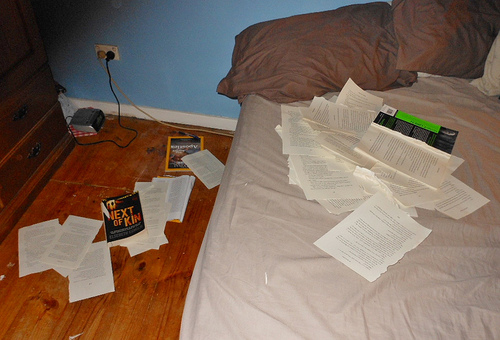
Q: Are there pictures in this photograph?
A: No, there are no pictures.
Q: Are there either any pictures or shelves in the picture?
A: No, there are no pictures or shelves.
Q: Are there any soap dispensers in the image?
A: No, there are no soap dispensers.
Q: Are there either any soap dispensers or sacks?
A: No, there are no soap dispensers or sacks.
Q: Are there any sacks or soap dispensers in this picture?
A: No, there are no soap dispensers or sacks.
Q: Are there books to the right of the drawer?
A: Yes, there is a book to the right of the drawer.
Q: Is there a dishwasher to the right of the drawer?
A: No, there is a book to the right of the drawer.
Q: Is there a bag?
A: No, there are no bags.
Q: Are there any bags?
A: No, there are no bags.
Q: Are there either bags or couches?
A: No, there are no bags or couches.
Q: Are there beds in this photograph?
A: Yes, there is a bed.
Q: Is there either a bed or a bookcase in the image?
A: Yes, there is a bed.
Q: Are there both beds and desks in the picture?
A: No, there is a bed but no desks.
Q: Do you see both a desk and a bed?
A: No, there is a bed but no desks.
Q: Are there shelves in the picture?
A: No, there are no shelves.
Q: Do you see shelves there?
A: No, there are no shelves.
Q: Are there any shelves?
A: No, there are no shelves.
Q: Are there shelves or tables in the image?
A: No, there are no shelves or tables.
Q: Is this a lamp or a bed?
A: This is a bed.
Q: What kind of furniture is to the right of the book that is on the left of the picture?
A: The piece of furniture is a bed.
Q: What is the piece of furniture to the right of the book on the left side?
A: The piece of furniture is a bed.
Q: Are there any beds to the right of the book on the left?
A: Yes, there is a bed to the right of the book.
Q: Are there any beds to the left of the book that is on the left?
A: No, the bed is to the right of the book.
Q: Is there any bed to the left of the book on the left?
A: No, the bed is to the right of the book.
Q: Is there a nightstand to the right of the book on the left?
A: No, there is a bed to the right of the book.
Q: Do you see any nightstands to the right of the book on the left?
A: No, there is a bed to the right of the book.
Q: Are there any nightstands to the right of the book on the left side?
A: No, there is a bed to the right of the book.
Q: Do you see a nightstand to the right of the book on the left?
A: No, there is a bed to the right of the book.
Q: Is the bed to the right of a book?
A: Yes, the bed is to the right of a book.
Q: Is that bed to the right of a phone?
A: No, the bed is to the right of a book.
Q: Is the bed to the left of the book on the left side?
A: No, the bed is to the right of the book.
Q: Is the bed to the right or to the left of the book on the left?
A: The bed is to the right of the book.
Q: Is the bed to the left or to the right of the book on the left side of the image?
A: The bed is to the right of the book.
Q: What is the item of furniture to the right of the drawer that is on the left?
A: The piece of furniture is a bed.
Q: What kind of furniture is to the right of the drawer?
A: The piece of furniture is a bed.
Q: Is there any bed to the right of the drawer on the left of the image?
A: Yes, there is a bed to the right of the drawer.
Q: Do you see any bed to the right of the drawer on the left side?
A: Yes, there is a bed to the right of the drawer.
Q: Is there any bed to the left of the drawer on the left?
A: No, the bed is to the right of the drawer.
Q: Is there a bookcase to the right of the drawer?
A: No, there is a bed to the right of the drawer.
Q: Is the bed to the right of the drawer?
A: Yes, the bed is to the right of the drawer.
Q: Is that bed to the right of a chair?
A: No, the bed is to the right of the drawer.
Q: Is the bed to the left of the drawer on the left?
A: No, the bed is to the right of the drawer.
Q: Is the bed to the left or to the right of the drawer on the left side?
A: The bed is to the right of the drawer.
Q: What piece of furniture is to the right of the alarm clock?
A: The piece of furniture is a bed.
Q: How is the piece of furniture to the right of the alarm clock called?
A: The piece of furniture is a bed.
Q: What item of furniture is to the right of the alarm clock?
A: The piece of furniture is a bed.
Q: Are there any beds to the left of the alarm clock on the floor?
A: No, the bed is to the right of the alarm clock.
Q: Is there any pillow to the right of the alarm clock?
A: No, there is a bed to the right of the alarm clock.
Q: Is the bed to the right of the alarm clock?
A: Yes, the bed is to the right of the alarm clock.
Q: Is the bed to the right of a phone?
A: No, the bed is to the right of the alarm clock.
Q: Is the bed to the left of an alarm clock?
A: No, the bed is to the right of an alarm clock.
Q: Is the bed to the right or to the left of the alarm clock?
A: The bed is to the right of the alarm clock.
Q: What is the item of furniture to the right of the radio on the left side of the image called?
A: The piece of furniture is a bed.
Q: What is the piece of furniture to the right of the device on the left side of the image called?
A: The piece of furniture is a bed.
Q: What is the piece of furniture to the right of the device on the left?
A: The piece of furniture is a bed.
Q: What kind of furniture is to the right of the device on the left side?
A: The piece of furniture is a bed.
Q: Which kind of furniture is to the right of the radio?
A: The piece of furniture is a bed.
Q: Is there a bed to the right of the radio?
A: Yes, there is a bed to the right of the radio.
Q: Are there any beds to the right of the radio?
A: Yes, there is a bed to the right of the radio.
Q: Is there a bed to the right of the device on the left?
A: Yes, there is a bed to the right of the radio.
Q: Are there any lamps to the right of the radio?
A: No, there is a bed to the right of the radio.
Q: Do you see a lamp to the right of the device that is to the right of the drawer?
A: No, there is a bed to the right of the radio.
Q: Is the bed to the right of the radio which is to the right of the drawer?
A: Yes, the bed is to the right of the radio.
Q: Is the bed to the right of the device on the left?
A: Yes, the bed is to the right of the radio.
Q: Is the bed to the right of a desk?
A: No, the bed is to the right of the radio.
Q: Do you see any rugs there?
A: No, there are no rugs.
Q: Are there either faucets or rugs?
A: No, there are no rugs or faucets.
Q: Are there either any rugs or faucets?
A: No, there are no rugs or faucets.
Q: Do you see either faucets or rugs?
A: No, there are no rugs or faucets.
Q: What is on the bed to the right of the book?
A: The paper is on the bed.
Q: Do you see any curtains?
A: No, there are no curtains.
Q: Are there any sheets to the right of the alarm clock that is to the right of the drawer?
A: Yes, there is a sheet to the right of the alarm clock.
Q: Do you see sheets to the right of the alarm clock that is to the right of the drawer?
A: Yes, there is a sheet to the right of the alarm clock.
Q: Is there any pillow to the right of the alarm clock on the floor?
A: No, there is a sheet to the right of the alarm clock.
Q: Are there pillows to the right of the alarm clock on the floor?
A: No, there is a sheet to the right of the alarm clock.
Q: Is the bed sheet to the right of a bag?
A: No, the bed sheet is to the right of the alarm clock.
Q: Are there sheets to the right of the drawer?
A: Yes, there is a sheet to the right of the drawer.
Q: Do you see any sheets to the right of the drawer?
A: Yes, there is a sheet to the right of the drawer.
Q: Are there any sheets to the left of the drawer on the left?
A: No, the sheet is to the right of the drawer.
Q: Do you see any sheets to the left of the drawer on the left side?
A: No, the sheet is to the right of the drawer.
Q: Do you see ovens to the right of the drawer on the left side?
A: No, there is a sheet to the right of the drawer.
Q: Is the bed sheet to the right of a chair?
A: No, the bed sheet is to the right of the drawer.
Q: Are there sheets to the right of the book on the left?
A: Yes, there is a sheet to the right of the book.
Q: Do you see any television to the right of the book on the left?
A: No, there is a sheet to the right of the book.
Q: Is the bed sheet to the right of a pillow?
A: No, the bed sheet is to the right of the book.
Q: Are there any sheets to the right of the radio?
A: Yes, there is a sheet to the right of the radio.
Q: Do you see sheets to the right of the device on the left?
A: Yes, there is a sheet to the right of the radio.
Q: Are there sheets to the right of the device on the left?
A: Yes, there is a sheet to the right of the radio.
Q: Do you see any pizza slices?
A: No, there are no pizza slices.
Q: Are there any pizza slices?
A: No, there are no pizza slices.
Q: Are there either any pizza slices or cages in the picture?
A: No, there are no pizza slices or cages.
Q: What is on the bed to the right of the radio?
A: The paper is on the bed.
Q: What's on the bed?
A: The paper is on the bed.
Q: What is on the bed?
A: The paper is on the bed.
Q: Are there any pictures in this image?
A: No, there are no pictures.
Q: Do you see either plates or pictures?
A: No, there are no pictures or plates.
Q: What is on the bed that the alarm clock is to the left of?
A: The paper is on the bed.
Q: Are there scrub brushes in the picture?
A: No, there are no scrub brushes.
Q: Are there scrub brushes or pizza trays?
A: No, there are no scrub brushes or pizza trays.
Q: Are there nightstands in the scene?
A: No, there are no nightstands.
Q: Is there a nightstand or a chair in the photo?
A: No, there are no nightstands or chairs.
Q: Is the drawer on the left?
A: Yes, the drawer is on the left of the image.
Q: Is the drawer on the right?
A: No, the drawer is on the left of the image.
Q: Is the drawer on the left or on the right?
A: The drawer is on the left of the image.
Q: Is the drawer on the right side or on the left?
A: The drawer is on the left of the image.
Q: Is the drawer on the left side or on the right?
A: The drawer is on the left of the image.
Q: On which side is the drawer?
A: The drawer is on the left of the image.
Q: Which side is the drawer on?
A: The drawer is on the left of the image.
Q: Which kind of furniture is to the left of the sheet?
A: The piece of furniture is a drawer.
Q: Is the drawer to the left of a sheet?
A: Yes, the drawer is to the left of a sheet.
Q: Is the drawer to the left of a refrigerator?
A: No, the drawer is to the left of a sheet.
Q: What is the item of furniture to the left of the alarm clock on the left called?
A: The piece of furniture is a drawer.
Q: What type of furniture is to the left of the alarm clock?
A: The piece of furniture is a drawer.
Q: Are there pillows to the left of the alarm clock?
A: No, there is a drawer to the left of the alarm clock.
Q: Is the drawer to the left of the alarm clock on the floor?
A: Yes, the drawer is to the left of the alarm clock.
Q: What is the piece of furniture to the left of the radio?
A: The piece of furniture is a drawer.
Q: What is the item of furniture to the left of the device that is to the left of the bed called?
A: The piece of furniture is a drawer.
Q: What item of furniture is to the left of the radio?
A: The piece of furniture is a drawer.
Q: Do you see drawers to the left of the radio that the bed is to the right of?
A: Yes, there is a drawer to the left of the radio.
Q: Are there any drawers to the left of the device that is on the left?
A: Yes, there is a drawer to the left of the radio.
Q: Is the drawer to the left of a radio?
A: Yes, the drawer is to the left of a radio.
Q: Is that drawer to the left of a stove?
A: No, the drawer is to the left of a radio.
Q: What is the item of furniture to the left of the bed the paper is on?
A: The piece of furniture is a drawer.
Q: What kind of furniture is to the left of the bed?
A: The piece of furniture is a drawer.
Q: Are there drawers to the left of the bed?
A: Yes, there is a drawer to the left of the bed.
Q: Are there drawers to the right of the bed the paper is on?
A: No, the drawer is to the left of the bed.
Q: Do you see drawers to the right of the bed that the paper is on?
A: No, the drawer is to the left of the bed.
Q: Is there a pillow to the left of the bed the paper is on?
A: No, there is a drawer to the left of the bed.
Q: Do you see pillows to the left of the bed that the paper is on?
A: No, there is a drawer to the left of the bed.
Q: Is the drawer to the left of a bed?
A: Yes, the drawer is to the left of a bed.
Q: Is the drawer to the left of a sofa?
A: No, the drawer is to the left of a bed.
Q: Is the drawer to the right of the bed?
A: No, the drawer is to the left of the bed.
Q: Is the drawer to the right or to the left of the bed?
A: The drawer is to the left of the bed.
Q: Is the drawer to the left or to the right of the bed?
A: The drawer is to the left of the bed.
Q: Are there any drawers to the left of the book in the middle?
A: Yes, there is a drawer to the left of the book.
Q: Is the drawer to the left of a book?
A: Yes, the drawer is to the left of a book.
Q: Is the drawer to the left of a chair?
A: No, the drawer is to the left of a book.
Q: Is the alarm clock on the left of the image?
A: Yes, the alarm clock is on the left of the image.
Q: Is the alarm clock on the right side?
A: No, the alarm clock is on the left of the image.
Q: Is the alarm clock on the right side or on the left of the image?
A: The alarm clock is on the left of the image.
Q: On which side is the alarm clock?
A: The alarm clock is on the left of the image.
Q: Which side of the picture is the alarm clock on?
A: The alarm clock is on the left of the image.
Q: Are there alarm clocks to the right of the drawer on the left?
A: Yes, there is an alarm clock to the right of the drawer.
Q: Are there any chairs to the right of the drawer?
A: No, there is an alarm clock to the right of the drawer.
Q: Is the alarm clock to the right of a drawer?
A: Yes, the alarm clock is to the right of a drawer.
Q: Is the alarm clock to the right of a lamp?
A: No, the alarm clock is to the right of a drawer.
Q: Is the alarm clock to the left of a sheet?
A: Yes, the alarm clock is to the left of a sheet.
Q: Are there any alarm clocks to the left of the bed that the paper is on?
A: Yes, there is an alarm clock to the left of the bed.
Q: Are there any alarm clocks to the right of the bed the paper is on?
A: No, the alarm clock is to the left of the bed.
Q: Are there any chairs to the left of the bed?
A: No, there is an alarm clock to the left of the bed.